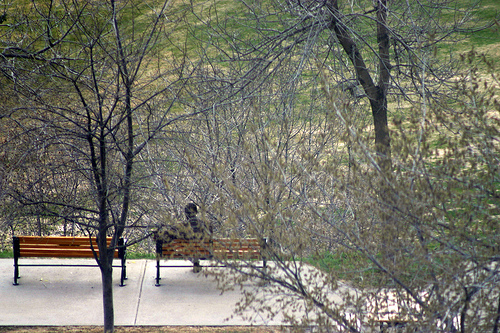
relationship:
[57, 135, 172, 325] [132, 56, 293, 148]
tree has branch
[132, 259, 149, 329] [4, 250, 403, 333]
crack in sidewalk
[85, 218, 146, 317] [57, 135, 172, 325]
stem of tree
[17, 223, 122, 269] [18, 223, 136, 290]
back of bench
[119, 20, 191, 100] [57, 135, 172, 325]
leaves of tree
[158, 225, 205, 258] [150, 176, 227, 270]
back of man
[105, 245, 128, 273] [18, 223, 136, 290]
edge of bench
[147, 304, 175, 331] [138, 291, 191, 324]
snow in ground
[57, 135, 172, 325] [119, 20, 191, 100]
tree with not leaves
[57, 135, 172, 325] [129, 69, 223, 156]
tree has branches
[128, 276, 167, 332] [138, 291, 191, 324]
crack in ground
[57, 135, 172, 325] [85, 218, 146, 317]
tree has trunk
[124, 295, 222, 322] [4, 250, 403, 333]
section of sidewalk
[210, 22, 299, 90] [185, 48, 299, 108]
grass on hill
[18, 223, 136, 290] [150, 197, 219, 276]
bench on man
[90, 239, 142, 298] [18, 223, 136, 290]
leg on bench